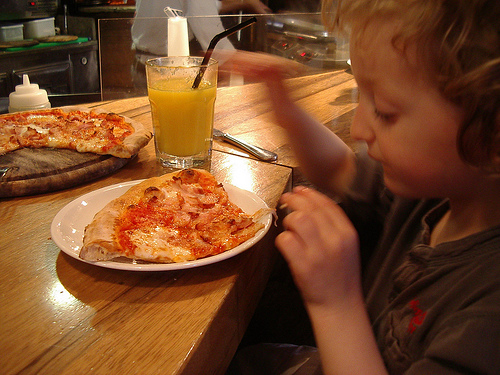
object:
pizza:
[79, 169, 280, 269]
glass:
[142, 52, 224, 181]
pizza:
[0, 106, 151, 160]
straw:
[193, 17, 260, 87]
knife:
[212, 127, 280, 163]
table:
[0, 69, 371, 374]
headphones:
[455, 114, 498, 169]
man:
[131, 1, 307, 80]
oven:
[265, 16, 356, 66]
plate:
[50, 176, 274, 273]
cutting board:
[0, 145, 134, 200]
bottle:
[7, 72, 52, 116]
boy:
[217, 0, 500, 374]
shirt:
[280, 144, 499, 375]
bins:
[22, 16, 56, 39]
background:
[0, 0, 351, 117]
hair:
[316, 0, 499, 137]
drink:
[146, 73, 217, 157]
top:
[14, 72, 40, 95]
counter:
[0, 38, 100, 56]